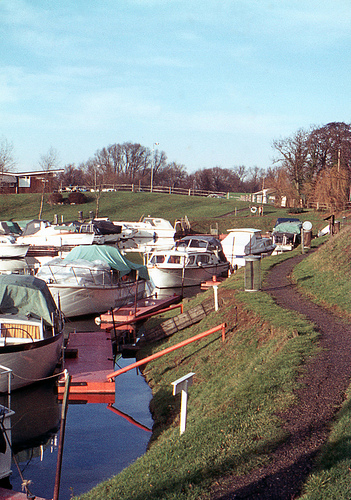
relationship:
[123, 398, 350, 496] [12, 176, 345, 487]
shadow on ground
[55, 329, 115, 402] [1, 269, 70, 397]
dock next to boat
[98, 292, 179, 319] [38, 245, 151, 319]
dock next to boat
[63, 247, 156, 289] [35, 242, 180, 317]
cover on boat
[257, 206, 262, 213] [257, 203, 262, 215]
jacket on pole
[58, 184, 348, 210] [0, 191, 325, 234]
fence along hill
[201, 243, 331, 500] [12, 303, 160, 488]
path along water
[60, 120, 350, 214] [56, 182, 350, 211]
tree behind fence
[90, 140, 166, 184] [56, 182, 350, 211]
tree behind fence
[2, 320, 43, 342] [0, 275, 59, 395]
curtains on boats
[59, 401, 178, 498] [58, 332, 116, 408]
water reflecting dock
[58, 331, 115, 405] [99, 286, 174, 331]
dock by dock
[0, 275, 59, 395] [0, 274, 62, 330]
boats has cover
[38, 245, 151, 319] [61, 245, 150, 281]
boat has cover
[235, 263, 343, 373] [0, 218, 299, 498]
path next to harbor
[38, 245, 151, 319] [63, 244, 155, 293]
boat with cover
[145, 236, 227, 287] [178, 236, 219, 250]
boat with cover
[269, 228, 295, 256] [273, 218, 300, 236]
boat with cover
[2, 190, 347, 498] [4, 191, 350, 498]
grass on ground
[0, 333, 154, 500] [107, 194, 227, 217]
water next to grass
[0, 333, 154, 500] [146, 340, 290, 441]
water next to grass